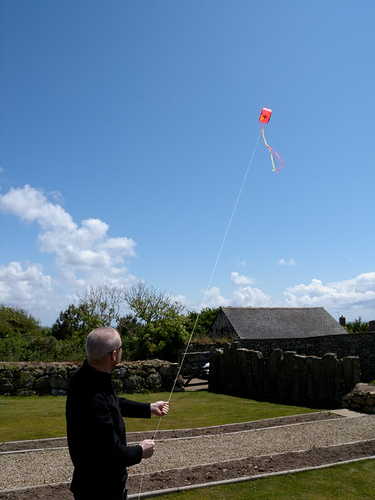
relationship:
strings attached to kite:
[259, 121, 286, 175] [260, 104, 271, 125]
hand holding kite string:
[151, 400, 169, 416] [140, 132, 263, 483]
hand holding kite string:
[139, 435, 156, 462] [140, 132, 263, 483]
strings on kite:
[259, 121, 287, 171] [260, 107, 272, 126]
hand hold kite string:
[139, 438, 156, 459] [135, 132, 261, 483]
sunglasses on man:
[104, 343, 125, 354] [63, 326, 170, 497]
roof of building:
[208, 296, 355, 337] [204, 290, 339, 395]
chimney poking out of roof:
[339, 314, 345, 328] [205, 303, 352, 344]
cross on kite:
[263, 112, 268, 120] [253, 91, 291, 133]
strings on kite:
[259, 121, 286, 175] [235, 88, 296, 166]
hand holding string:
[159, 394, 174, 409] [201, 135, 264, 258]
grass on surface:
[169, 369, 260, 438] [4, 384, 301, 438]